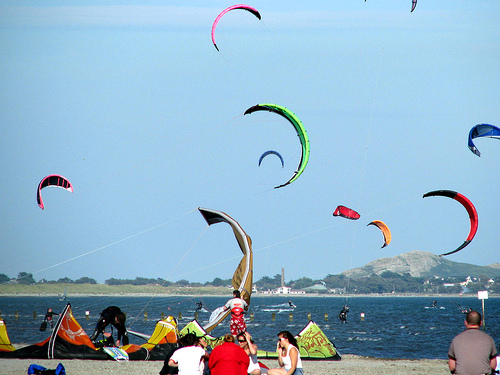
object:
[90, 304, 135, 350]
man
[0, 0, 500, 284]
sky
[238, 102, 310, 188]
kites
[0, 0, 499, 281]
air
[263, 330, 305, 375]
people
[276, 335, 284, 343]
sunglasses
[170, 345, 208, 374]
shirt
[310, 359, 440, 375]
sand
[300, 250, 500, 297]
mountain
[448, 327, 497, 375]
gray shirt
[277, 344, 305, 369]
white tank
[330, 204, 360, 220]
sail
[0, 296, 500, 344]
body of water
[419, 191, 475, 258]
kite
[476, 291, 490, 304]
sign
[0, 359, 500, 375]
beach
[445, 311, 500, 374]
man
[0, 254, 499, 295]
distance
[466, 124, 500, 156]
kite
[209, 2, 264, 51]
kite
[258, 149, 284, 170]
kite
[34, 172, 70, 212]
kite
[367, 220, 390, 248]
kite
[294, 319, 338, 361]
kite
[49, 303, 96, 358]
kite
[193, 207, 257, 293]
kite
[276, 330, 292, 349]
head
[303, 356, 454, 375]
ground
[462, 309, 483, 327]
head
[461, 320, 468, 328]
ear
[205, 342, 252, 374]
shirt